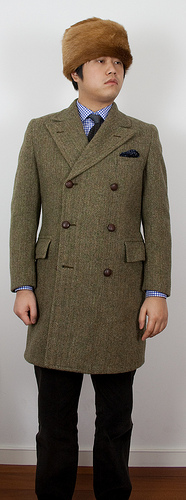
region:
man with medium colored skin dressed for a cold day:
[0, 16, 166, 497]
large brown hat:
[51, 13, 134, 80]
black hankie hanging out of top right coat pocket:
[116, 148, 141, 160]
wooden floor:
[143, 474, 179, 491]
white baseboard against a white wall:
[137, 447, 184, 466]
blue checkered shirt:
[70, 95, 108, 138]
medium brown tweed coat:
[47, 128, 129, 275]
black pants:
[33, 371, 128, 475]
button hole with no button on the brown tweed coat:
[57, 260, 74, 270]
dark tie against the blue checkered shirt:
[84, 113, 103, 145]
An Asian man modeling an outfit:
[6, 10, 185, 484]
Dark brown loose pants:
[32, 355, 136, 497]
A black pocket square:
[117, 147, 143, 161]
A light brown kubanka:
[56, 17, 143, 70]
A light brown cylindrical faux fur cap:
[54, 16, 145, 77]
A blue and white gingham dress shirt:
[73, 98, 113, 133]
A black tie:
[83, 111, 105, 142]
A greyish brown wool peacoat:
[9, 100, 171, 385]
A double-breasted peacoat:
[18, 97, 151, 375]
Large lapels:
[45, 98, 132, 169]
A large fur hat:
[58, 16, 139, 76]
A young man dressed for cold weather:
[8, 13, 176, 497]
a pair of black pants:
[33, 362, 132, 498]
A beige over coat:
[9, 111, 170, 374]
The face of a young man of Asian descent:
[64, 53, 130, 103]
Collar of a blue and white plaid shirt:
[74, 100, 116, 119]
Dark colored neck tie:
[87, 113, 102, 140]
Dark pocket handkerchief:
[119, 149, 141, 158]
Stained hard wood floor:
[1, 464, 185, 498]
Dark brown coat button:
[108, 182, 119, 191]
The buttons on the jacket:
[61, 178, 119, 276]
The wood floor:
[0, 463, 185, 499]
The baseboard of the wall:
[0, 444, 185, 470]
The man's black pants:
[31, 362, 134, 498]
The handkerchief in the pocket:
[117, 147, 140, 159]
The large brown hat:
[61, 15, 135, 79]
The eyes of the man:
[95, 57, 121, 66]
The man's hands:
[9, 287, 168, 343]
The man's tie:
[85, 113, 102, 143]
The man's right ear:
[70, 71, 79, 84]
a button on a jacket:
[62, 178, 72, 191]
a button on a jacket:
[107, 181, 117, 190]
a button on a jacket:
[60, 218, 71, 233]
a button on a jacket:
[105, 221, 114, 234]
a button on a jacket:
[102, 265, 110, 276]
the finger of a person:
[137, 304, 146, 329]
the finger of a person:
[141, 317, 154, 339]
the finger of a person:
[151, 322, 160, 338]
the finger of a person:
[27, 299, 37, 323]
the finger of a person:
[17, 308, 28, 327]